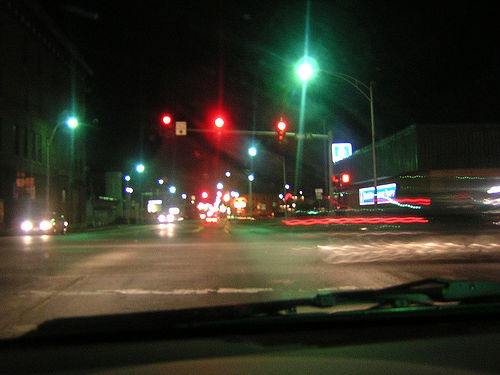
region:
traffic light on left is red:
[143, 98, 198, 158]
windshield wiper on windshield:
[128, 291, 260, 363]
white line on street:
[176, 268, 248, 322]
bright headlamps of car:
[28, 205, 75, 246]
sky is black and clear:
[441, 28, 471, 91]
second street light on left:
[126, 152, 171, 205]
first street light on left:
[46, 118, 85, 128]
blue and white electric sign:
[327, 138, 372, 169]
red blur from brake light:
[306, 216, 411, 246]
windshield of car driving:
[266, 215, 304, 243]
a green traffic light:
[279, 53, 346, 88]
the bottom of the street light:
[368, 187, 389, 214]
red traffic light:
[273, 118, 290, 144]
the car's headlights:
[22, 222, 64, 233]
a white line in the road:
[96, 277, 141, 301]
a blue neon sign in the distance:
[357, 187, 402, 207]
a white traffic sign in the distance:
[175, 121, 188, 139]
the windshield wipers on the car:
[293, 299, 348, 326]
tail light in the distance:
[205, 212, 219, 222]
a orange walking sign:
[340, 172, 355, 183]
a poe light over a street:
[282, 53, 412, 215]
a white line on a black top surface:
[16, 276, 292, 308]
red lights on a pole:
[160, 107, 328, 145]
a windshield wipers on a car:
[85, 259, 494, 350]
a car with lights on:
[18, 208, 65, 245]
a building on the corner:
[345, 121, 477, 217]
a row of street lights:
[127, 164, 206, 213]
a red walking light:
[333, 169, 353, 190]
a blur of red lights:
[286, 216, 461, 225]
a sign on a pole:
[166, 116, 193, 148]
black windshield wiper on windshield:
[27, 274, 429, 314]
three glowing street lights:
[60, 46, 323, 177]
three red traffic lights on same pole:
[155, 95, 285, 145]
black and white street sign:
[170, 115, 185, 135]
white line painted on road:
[32, 277, 257, 297]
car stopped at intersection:
[6, 210, 66, 235]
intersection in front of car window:
[26, 215, 403, 295]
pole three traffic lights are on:
[165, 120, 321, 142]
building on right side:
[320, 113, 494, 217]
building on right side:
[13, 39, 95, 184]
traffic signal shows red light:
[211, 110, 228, 145]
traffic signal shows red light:
[272, 117, 294, 152]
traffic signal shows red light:
[158, 111, 177, 143]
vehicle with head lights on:
[23, 212, 80, 250]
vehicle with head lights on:
[156, 209, 180, 225]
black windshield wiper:
[42, 272, 495, 329]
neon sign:
[357, 184, 409, 206]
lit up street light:
[286, 50, 379, 98]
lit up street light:
[56, 107, 92, 144]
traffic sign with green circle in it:
[175, 117, 190, 137]